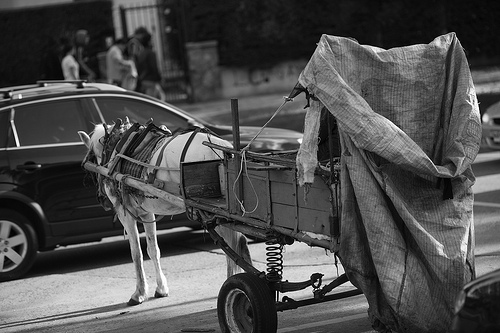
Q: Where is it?
A: This is at the road.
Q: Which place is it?
A: It is a road.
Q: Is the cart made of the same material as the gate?
A: No, the cart is made of wood and the gate is made of metal.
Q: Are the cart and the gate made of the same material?
A: No, the cart is made of wood and the gate is made of metal.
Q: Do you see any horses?
A: Yes, there is a horse.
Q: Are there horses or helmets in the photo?
A: Yes, there is a horse.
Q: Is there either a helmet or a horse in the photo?
A: Yes, there is a horse.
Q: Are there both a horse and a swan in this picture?
A: No, there is a horse but no swans.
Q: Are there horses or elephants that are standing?
A: Yes, the horse is standing.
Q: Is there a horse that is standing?
A: Yes, there is a horse that is standing.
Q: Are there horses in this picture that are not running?
A: Yes, there is a horse that is standing.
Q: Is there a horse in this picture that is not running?
A: Yes, there is a horse that is standing.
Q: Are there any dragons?
A: No, there are no dragons.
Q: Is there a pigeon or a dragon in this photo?
A: No, there are no dragons or pigeons.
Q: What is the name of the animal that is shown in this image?
A: The animal is a horse.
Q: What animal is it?
A: The animal is a horse.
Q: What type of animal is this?
A: This is a horse.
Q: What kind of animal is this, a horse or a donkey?
A: This is a horse.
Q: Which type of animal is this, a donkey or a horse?
A: This is a horse.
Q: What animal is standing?
A: The animal is a horse.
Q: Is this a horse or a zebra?
A: This is a horse.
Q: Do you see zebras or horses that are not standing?
A: No, there is a horse but it is standing.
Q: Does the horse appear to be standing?
A: Yes, the horse is standing.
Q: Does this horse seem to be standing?
A: Yes, the horse is standing.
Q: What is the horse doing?
A: The horse is standing.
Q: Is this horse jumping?
A: No, the horse is standing.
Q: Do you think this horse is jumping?
A: No, the horse is standing.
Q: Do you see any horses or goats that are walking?
A: No, there is a horse but it is standing.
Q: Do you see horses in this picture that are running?
A: No, there is a horse but it is standing.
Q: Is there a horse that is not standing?
A: No, there is a horse but it is standing.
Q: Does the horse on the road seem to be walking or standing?
A: The horse is standing.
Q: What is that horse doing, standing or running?
A: The horse is standing.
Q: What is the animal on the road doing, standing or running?
A: The horse is standing.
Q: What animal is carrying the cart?
A: The horse is carrying the cart.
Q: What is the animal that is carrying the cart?
A: The animal is a horse.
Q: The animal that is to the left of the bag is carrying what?
A: The horse is carrying a cart.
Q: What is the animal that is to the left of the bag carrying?
A: The horse is carrying a cart.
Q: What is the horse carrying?
A: The horse is carrying a cart.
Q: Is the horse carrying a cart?
A: Yes, the horse is carrying a cart.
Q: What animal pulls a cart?
A: The horse pulls a cart.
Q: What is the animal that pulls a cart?
A: The animal is a horse.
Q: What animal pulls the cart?
A: The animal is a horse.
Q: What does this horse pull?
A: The horse pulls a cart.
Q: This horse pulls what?
A: The horse pulls a cart.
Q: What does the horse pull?
A: The horse pulls a cart.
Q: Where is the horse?
A: The horse is on the road.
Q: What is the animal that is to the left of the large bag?
A: The animal is a horse.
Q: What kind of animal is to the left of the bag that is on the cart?
A: The animal is a horse.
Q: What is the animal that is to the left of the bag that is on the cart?
A: The animal is a horse.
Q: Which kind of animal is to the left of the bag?
A: The animal is a horse.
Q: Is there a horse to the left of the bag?
A: Yes, there is a horse to the left of the bag.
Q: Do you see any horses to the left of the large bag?
A: Yes, there is a horse to the left of the bag.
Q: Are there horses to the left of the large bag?
A: Yes, there is a horse to the left of the bag.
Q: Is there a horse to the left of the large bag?
A: Yes, there is a horse to the left of the bag.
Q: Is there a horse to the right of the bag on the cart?
A: No, the horse is to the left of the bag.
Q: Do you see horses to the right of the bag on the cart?
A: No, the horse is to the left of the bag.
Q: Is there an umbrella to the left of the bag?
A: No, there is a horse to the left of the bag.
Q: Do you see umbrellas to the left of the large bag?
A: No, there is a horse to the left of the bag.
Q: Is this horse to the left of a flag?
A: No, the horse is to the left of a bag.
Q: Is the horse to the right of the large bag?
A: No, the horse is to the left of the bag.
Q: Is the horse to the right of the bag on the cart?
A: No, the horse is to the left of the bag.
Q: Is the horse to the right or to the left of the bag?
A: The horse is to the left of the bag.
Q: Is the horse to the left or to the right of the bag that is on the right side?
A: The horse is to the left of the bag.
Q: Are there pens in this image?
A: No, there are no pens.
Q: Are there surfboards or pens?
A: No, there are no pens or surfboards.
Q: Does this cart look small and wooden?
A: Yes, the cart is small and wooden.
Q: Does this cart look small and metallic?
A: No, the cart is small but wooden.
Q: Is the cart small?
A: Yes, the cart is small.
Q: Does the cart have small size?
A: Yes, the cart is small.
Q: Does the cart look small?
A: Yes, the cart is small.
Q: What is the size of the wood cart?
A: The cart is small.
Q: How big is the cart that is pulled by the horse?
A: The cart is small.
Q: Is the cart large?
A: No, the cart is small.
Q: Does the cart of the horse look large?
A: No, the cart is small.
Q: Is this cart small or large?
A: The cart is small.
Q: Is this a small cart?
A: Yes, this is a small cart.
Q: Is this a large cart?
A: No, this is a small cart.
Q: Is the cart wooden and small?
A: Yes, the cart is wooden and small.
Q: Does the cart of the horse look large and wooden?
A: No, the cart is wooden but small.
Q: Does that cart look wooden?
A: Yes, the cart is wooden.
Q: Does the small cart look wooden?
A: Yes, the cart is wooden.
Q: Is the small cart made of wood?
A: Yes, the cart is made of wood.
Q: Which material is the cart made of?
A: The cart is made of wood.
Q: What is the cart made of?
A: The cart is made of wood.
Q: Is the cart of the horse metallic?
A: No, the cart is wooden.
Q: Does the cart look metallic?
A: No, the cart is wooden.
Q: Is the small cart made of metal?
A: No, the cart is made of wood.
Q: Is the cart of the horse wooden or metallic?
A: The cart is wooden.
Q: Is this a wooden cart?
A: Yes, this is a wooden cart.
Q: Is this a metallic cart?
A: No, this is a wooden cart.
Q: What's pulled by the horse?
A: The cart is pulled by the horse.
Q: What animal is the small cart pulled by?
A: The cart is pulled by the horse.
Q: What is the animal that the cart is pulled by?
A: The animal is a horse.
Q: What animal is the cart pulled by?
A: The cart is pulled by the horse.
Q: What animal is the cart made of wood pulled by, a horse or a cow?
A: The cart is pulled by a horse.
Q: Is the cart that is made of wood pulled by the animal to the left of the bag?
A: Yes, the cart is pulled by the horse.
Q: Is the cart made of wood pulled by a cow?
A: No, the cart is pulled by the horse.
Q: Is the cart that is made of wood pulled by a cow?
A: No, the cart is pulled by the horse.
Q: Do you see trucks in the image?
A: No, there are no trucks.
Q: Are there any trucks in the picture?
A: No, there are no trucks.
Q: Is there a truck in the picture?
A: No, there are no trucks.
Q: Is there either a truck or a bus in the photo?
A: No, there are no trucks or buses.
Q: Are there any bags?
A: Yes, there is a bag.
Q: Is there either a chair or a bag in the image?
A: Yes, there is a bag.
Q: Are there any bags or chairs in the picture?
A: Yes, there is a bag.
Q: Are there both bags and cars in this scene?
A: Yes, there are both a bag and a car.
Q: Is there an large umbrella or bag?
A: Yes, there is a large bag.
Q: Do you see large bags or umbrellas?
A: Yes, there is a large bag.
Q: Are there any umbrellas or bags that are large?
A: Yes, the bag is large.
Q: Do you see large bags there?
A: Yes, there is a large bag.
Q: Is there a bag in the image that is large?
A: Yes, there is a large bag.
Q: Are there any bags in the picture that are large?
A: Yes, there is a bag that is large.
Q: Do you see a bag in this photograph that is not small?
A: Yes, there is a large bag.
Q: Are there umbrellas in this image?
A: No, there are no umbrellas.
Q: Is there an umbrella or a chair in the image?
A: No, there are no umbrellas or chairs.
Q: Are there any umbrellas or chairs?
A: No, there are no umbrellas or chairs.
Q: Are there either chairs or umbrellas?
A: No, there are no umbrellas or chairs.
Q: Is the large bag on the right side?
A: Yes, the bag is on the right of the image.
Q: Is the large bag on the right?
A: Yes, the bag is on the right of the image.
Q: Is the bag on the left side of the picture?
A: No, the bag is on the right of the image.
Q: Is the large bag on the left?
A: No, the bag is on the right of the image.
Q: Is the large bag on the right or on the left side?
A: The bag is on the right of the image.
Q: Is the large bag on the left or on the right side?
A: The bag is on the right of the image.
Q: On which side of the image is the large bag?
A: The bag is on the right of the image.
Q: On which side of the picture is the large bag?
A: The bag is on the right of the image.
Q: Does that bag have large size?
A: Yes, the bag is large.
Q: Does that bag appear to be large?
A: Yes, the bag is large.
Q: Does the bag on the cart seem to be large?
A: Yes, the bag is large.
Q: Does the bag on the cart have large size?
A: Yes, the bag is large.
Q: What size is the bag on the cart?
A: The bag is large.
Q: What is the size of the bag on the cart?
A: The bag is large.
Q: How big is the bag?
A: The bag is large.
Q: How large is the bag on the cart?
A: The bag is large.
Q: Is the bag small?
A: No, the bag is large.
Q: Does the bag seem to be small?
A: No, the bag is large.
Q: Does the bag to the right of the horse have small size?
A: No, the bag is large.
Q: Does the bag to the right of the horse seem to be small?
A: No, the bag is large.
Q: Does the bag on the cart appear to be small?
A: No, the bag is large.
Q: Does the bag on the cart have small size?
A: No, the bag is large.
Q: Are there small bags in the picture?
A: No, there is a bag but it is large.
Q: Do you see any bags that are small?
A: No, there is a bag but it is large.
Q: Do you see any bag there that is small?
A: No, there is a bag but it is large.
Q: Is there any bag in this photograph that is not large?
A: No, there is a bag but it is large.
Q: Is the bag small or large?
A: The bag is large.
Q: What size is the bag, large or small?
A: The bag is large.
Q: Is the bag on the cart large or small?
A: The bag is large.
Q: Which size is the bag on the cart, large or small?
A: The bag is large.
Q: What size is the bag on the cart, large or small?
A: The bag is large.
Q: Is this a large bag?
A: Yes, this is a large bag.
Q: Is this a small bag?
A: No, this is a large bag.